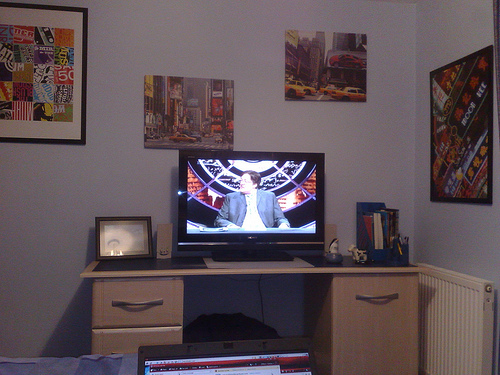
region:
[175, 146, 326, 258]
The TV is turned on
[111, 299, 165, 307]
Handle is made of metal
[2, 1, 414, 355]
The wall is gray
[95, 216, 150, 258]
Picture frame is black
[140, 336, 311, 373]
Laptop in the foreground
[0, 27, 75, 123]
Picture of jumbled images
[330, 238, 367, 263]
Toys on the desk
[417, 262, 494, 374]
The radiator is white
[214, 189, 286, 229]
The jacket is gray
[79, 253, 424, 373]
Desk is light colored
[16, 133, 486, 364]
desk in corner of room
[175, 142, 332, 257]
man talking in front of curved design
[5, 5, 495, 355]
artwork on white walls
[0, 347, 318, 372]
edges of pillow and books in front of desk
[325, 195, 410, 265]
figurines and books and top of desk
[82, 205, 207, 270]
framed certificate and box on black mat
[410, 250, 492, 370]
ridged panel against wall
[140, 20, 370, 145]
hanging pictures of traffic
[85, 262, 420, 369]
drawers with handles under desktop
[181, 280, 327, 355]
dark objects in space under desk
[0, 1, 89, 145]
A framed picture on a wall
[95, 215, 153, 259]
A framed picture on a desk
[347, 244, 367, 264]
A small animal figurine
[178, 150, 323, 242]
A television playing on a desk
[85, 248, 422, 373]
A small brown wooden desk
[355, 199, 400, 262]
A small rack filled with books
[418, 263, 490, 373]
A small white radiator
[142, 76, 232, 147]
A unframed picture on a wall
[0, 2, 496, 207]
Several picyures on a white wall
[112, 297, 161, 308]
A small metal drawer handle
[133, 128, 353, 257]
television that is turned on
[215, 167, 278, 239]
person on the television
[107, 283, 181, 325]
handle on the droor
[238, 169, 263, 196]
head of a man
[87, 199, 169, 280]
photo next to television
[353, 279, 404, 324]
handle on the cabinet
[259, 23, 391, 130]
photo on the wall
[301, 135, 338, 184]
corner of the television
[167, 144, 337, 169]
top of the television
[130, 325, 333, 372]
laptop in the photo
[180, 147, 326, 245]
a television that is turned on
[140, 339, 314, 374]
the top of a laptop on the bed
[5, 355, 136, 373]
bed with a blue cover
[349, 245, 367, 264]
cow on the desk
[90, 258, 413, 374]
a small wooden desk in the corner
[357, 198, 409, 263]
two blue magazine holders on the desk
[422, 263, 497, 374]
a radiator on the wall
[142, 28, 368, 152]
two posters of taxis in Times Square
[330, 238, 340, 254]
a figurine of a nun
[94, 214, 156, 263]
a framed certificate on the desk